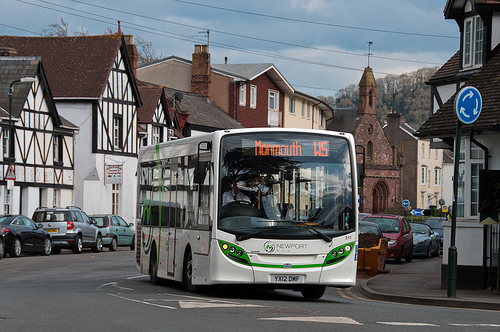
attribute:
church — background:
[325, 41, 403, 214]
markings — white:
[142, 289, 268, 309]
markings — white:
[258, 315, 362, 325]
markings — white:
[101, 262, 495, 330]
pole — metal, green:
[441, 114, 463, 296]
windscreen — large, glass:
[214, 122, 380, 259]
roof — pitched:
[1, 30, 146, 108]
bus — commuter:
[130, 129, 364, 299]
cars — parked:
[15, 209, 152, 240]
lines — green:
[211, 233, 371, 280]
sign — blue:
[448, 82, 488, 124]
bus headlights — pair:
[223, 243, 244, 259]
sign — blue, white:
[443, 81, 488, 129]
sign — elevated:
[102, 161, 125, 186]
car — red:
[335, 172, 460, 302]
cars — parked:
[364, 189, 447, 266]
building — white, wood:
[3, 28, 154, 222]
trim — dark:
[90, 44, 140, 157]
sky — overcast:
[38, 5, 464, 76]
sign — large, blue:
[456, 82, 484, 122]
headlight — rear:
[206, 235, 245, 263]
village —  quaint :
[2, 1, 497, 326]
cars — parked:
[1, 203, 138, 259]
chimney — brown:
[189, 42, 210, 98]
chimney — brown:
[385, 112, 405, 126]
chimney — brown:
[0, 48, 17, 55]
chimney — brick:
[187, 40, 217, 98]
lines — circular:
[458, 89, 480, 117]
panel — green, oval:
[321, 239, 357, 269]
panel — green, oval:
[218, 238, 254, 264]